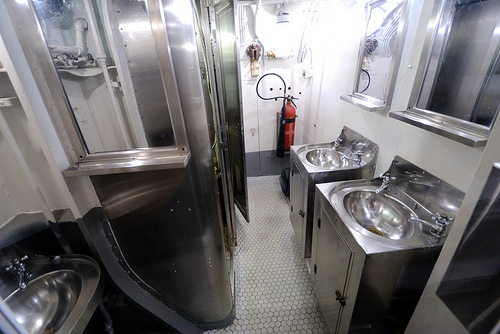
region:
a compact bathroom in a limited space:
[3, 3, 496, 329]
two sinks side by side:
[288, 121, 456, 330]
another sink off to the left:
[0, 237, 107, 329]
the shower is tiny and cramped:
[8, 2, 240, 332]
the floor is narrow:
[230, 165, 323, 331]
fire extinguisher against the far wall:
[253, 67, 300, 157]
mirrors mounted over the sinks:
[333, 0, 498, 155]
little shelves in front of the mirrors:
[338, 88, 488, 148]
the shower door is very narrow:
[202, 0, 259, 235]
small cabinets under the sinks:
[288, 150, 364, 332]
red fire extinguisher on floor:
[253, 72, 313, 172]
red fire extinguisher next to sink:
[252, 69, 387, 264]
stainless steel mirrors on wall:
[335, 0, 499, 156]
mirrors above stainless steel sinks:
[291, 0, 498, 272]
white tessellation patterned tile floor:
[233, 155, 330, 332]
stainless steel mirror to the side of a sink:
[3, 0, 243, 330]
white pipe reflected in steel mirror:
[27, 32, 192, 185]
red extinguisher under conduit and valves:
[236, 3, 335, 182]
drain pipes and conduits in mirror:
[0, 2, 135, 92]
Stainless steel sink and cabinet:
[297, 154, 481, 331]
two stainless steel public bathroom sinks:
[291, 114, 459, 286]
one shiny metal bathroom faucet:
[409, 206, 453, 238]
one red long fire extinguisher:
[256, 70, 298, 157]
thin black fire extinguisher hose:
[253, 69, 298, 104]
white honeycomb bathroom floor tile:
[242, 253, 302, 328]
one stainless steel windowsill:
[63, 152, 195, 177]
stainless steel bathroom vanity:
[310, 154, 462, 333]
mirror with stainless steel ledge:
[394, 0, 499, 151]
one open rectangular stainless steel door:
[214, 3, 256, 225]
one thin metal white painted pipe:
[3, 116, 64, 230]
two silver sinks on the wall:
[282, 119, 466, 332]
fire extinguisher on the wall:
[257, 73, 299, 157]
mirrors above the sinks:
[354, 2, 497, 127]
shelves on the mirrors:
[340, 90, 482, 147]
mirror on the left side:
[20, 0, 200, 175]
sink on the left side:
[0, 240, 113, 332]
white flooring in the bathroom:
[237, 160, 330, 332]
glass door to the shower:
[206, 2, 266, 227]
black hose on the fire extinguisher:
[252, 67, 287, 149]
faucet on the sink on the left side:
[2, 254, 31, 290]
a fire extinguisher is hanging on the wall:
[253, 67, 300, 160]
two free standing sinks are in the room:
[275, 133, 420, 332]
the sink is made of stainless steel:
[303, 168, 458, 333]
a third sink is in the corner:
[1, 243, 105, 332]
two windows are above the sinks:
[343, 1, 490, 152]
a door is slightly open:
[205, 3, 260, 228]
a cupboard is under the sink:
[226, 160, 287, 321]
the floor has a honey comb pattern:
[247, 178, 315, 332]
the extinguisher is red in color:
[277, 91, 296, 155]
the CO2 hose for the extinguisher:
[258, 70, 289, 161]